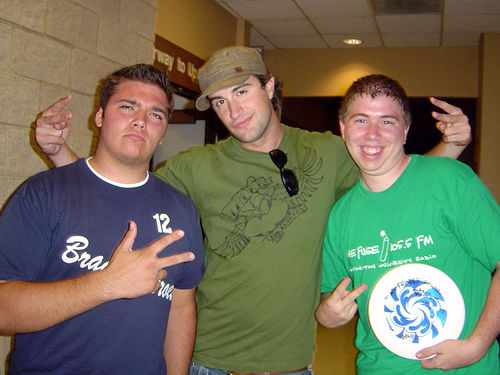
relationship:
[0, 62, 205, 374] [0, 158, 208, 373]
boy wearing t-shirt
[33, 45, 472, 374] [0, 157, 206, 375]
boy wearing blue shirt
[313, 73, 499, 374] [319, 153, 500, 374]
boy wearing shirt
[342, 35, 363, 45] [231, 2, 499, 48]
light on ceiling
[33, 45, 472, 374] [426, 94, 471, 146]
boy holding hand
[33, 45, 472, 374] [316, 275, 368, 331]
boy holding signs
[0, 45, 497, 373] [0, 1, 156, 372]
men next to wall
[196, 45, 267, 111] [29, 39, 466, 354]
green hat on man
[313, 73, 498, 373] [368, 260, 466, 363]
boy holding frisbee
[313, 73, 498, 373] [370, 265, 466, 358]
boy holding frisbee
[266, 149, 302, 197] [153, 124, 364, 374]
sunglasses on man's shirt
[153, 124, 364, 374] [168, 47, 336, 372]
man's shirt on man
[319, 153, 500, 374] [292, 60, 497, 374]
shirt on boy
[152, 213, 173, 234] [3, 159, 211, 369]
12 on shirt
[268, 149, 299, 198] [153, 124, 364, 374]
sunglasses in man's shirt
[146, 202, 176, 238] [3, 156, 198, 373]
12 on blue shirt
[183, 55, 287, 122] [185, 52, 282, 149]
green hat on head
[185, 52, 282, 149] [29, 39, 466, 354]
head of man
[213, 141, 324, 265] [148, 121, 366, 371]
design on man's shirt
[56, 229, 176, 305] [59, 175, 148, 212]
writing on shirt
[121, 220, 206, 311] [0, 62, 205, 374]
hand of boy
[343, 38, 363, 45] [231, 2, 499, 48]
light in ceiling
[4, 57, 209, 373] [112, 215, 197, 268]
boy with fingers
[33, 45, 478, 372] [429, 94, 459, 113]
boy with finger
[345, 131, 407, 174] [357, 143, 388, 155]
smiling with teeth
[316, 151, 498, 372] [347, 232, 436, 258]
shirt for radio station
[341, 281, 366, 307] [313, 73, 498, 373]
finger on boy